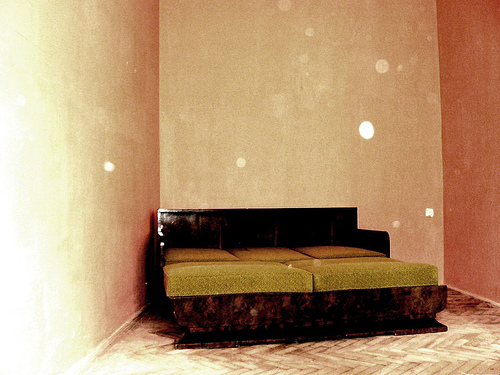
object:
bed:
[155, 205, 457, 338]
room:
[0, 0, 500, 375]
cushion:
[161, 262, 312, 297]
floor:
[62, 308, 500, 375]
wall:
[158, 0, 445, 286]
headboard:
[154, 206, 358, 248]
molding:
[449, 285, 498, 306]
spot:
[376, 59, 390, 74]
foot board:
[172, 285, 449, 350]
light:
[156, 209, 174, 222]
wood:
[156, 208, 391, 261]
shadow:
[138, 211, 155, 319]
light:
[0, 98, 21, 331]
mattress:
[162, 244, 440, 297]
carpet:
[172, 321, 459, 351]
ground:
[0, 284, 499, 375]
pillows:
[168, 247, 312, 263]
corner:
[430, 51, 448, 61]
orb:
[358, 121, 376, 140]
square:
[425, 208, 435, 218]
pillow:
[166, 247, 240, 262]